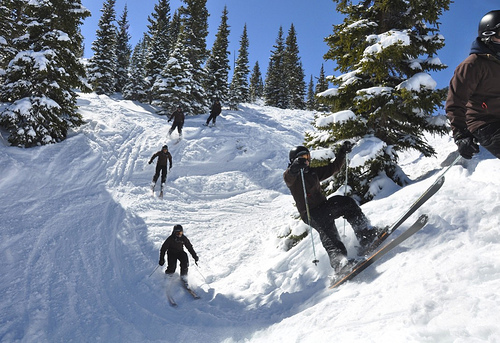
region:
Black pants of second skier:
[313, 210, 369, 245]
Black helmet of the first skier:
[486, 16, 496, 35]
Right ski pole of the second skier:
[296, 170, 317, 263]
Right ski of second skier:
[336, 210, 441, 295]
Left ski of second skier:
[336, 157, 358, 247]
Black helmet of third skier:
[176, 223, 183, 231]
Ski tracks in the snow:
[36, 265, 64, 293]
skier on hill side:
[145, 211, 217, 303]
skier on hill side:
[267, 125, 409, 265]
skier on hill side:
[138, 145, 198, 205]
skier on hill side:
[148, 105, 195, 130]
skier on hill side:
[207, 79, 235, 126]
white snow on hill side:
[50, 219, 87, 254]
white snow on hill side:
[65, 266, 90, 281]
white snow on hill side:
[240, 242, 257, 266]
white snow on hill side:
[374, 306, 435, 341]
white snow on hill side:
[31, 181, 102, 268]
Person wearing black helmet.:
[287, 147, 317, 159]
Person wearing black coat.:
[283, 180, 307, 199]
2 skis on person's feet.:
[329, 214, 431, 299]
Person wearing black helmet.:
[160, 220, 192, 233]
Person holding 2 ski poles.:
[159, 258, 220, 283]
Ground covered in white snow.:
[47, 248, 127, 333]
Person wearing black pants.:
[153, 261, 214, 284]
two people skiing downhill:
[148, 95, 189, 217]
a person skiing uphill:
[257, 138, 487, 288]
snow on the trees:
[6, 0, 77, 144]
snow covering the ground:
[21, 115, 282, 327]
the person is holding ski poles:
[280, 140, 356, 267]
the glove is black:
[452, 127, 480, 164]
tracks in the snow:
[70, 140, 147, 321]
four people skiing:
[132, 91, 233, 325]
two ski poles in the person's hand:
[147, 250, 210, 283]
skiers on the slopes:
[39, 30, 484, 316]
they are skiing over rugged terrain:
[29, 56, 458, 308]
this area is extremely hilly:
[44, 79, 399, 316]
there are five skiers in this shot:
[128, 61, 439, 295]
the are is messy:
[24, 121, 144, 286]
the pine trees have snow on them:
[114, 7, 305, 106]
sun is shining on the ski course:
[79, 15, 460, 300]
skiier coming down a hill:
[268, 136, 432, 282]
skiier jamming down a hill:
[264, 121, 444, 271]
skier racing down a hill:
[265, 127, 445, 272]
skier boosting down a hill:
[275, 120, 431, 267]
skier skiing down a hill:
[273, 129, 450, 267]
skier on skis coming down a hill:
[260, 130, 417, 268]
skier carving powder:
[281, 135, 429, 285]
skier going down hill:
[281, 110, 423, 288]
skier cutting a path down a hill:
[264, 120, 432, 267]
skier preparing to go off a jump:
[265, 112, 438, 272]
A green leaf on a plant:
[50, 18, 52, 20]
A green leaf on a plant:
[54, 20, 59, 22]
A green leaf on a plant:
[10, 28, 13, 30]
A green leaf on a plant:
[189, 34, 201, 41]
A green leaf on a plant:
[290, 54, 291, 56]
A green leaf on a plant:
[348, 45, 350, 47]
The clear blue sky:
[80, 0, 493, 134]